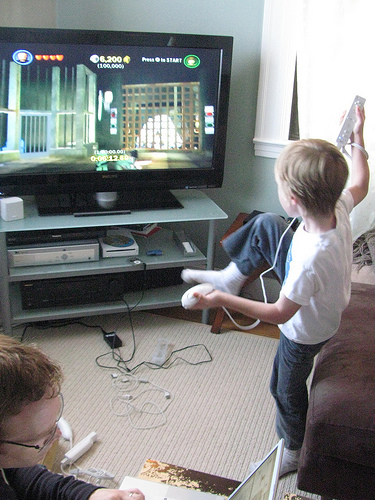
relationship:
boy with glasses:
[0, 335, 145, 498] [12, 407, 81, 439]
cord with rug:
[86, 334, 177, 424] [52, 314, 269, 472]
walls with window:
[194, 6, 262, 128] [239, 0, 361, 184]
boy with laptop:
[0, 335, 145, 498] [124, 431, 298, 498]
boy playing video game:
[175, 91, 372, 487] [92, 234, 142, 263]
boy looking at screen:
[0, 335, 145, 498] [226, 456, 281, 495]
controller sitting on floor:
[62, 434, 117, 467] [96, 404, 168, 455]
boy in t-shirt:
[175, 91, 372, 487] [261, 218, 357, 353]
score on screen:
[97, 52, 131, 70] [11, 31, 225, 185]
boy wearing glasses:
[0, 335, 145, 498] [22, 403, 80, 454]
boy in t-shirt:
[220, 159, 338, 466] [279, 195, 360, 345]